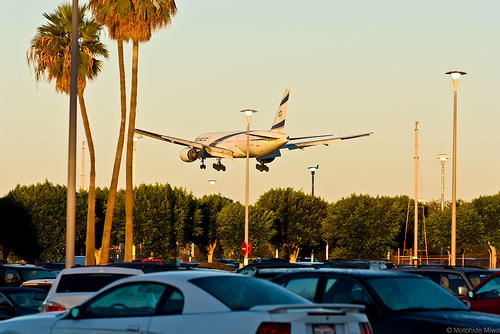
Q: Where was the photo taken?
A: It was taken at the parking lot.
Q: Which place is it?
A: It is a parking lot.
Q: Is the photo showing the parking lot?
A: Yes, it is showing the parking lot.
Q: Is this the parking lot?
A: Yes, it is the parking lot.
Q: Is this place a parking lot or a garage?
A: It is a parking lot.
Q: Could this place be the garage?
A: No, it is the parking lot.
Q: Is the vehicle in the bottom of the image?
A: Yes, the vehicle is in the bottom of the image.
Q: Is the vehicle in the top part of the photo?
A: No, the vehicle is in the bottom of the image.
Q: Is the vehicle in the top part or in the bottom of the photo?
A: The vehicle is in the bottom of the image.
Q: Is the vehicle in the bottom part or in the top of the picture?
A: The vehicle is in the bottom of the image.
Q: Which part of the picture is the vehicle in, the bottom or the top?
A: The vehicle is in the bottom of the image.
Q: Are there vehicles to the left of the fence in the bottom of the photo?
A: Yes, there is a vehicle to the left of the fence.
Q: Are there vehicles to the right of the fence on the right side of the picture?
A: No, the vehicle is to the left of the fence.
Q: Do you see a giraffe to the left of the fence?
A: No, there is a vehicle to the left of the fence.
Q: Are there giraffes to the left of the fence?
A: No, there is a vehicle to the left of the fence.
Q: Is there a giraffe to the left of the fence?
A: No, there is a vehicle to the left of the fence.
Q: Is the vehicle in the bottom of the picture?
A: Yes, the vehicle is in the bottom of the image.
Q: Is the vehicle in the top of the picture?
A: No, the vehicle is in the bottom of the image.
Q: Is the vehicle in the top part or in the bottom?
A: The vehicle is in the bottom of the image.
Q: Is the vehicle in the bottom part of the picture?
A: Yes, the vehicle is in the bottom of the image.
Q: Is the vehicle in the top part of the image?
A: No, the vehicle is in the bottom of the image.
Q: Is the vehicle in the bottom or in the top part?
A: The vehicle is in the bottom of the image.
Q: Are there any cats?
A: No, there are no cats.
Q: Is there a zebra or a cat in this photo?
A: No, there are no cats or zebras.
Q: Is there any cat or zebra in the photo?
A: No, there are no cats or zebras.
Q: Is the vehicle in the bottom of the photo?
A: Yes, the vehicle is in the bottom of the image.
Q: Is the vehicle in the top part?
A: No, the vehicle is in the bottom of the image.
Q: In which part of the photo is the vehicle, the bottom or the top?
A: The vehicle is in the bottom of the image.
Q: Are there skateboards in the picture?
A: No, there are no skateboards.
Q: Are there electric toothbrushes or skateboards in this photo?
A: No, there are no skateboards or electric toothbrushes.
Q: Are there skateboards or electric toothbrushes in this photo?
A: No, there are no skateboards or electric toothbrushes.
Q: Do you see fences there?
A: Yes, there is a fence.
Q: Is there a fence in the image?
A: Yes, there is a fence.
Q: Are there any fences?
A: Yes, there is a fence.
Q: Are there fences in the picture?
A: Yes, there is a fence.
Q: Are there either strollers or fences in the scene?
A: Yes, there is a fence.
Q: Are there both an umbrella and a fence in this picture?
A: No, there is a fence but no umbrellas.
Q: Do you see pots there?
A: No, there are no pots.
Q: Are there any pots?
A: No, there are no pots.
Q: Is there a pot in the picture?
A: No, there are no pots.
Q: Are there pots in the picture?
A: No, there are no pots.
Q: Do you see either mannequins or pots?
A: No, there are no pots or mannequins.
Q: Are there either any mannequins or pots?
A: No, there are no pots or mannequins.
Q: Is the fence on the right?
A: Yes, the fence is on the right of the image.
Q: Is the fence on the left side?
A: No, the fence is on the right of the image.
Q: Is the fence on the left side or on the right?
A: The fence is on the right of the image.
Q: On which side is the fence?
A: The fence is on the right of the image.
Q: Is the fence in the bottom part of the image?
A: Yes, the fence is in the bottom of the image.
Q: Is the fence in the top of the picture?
A: No, the fence is in the bottom of the image.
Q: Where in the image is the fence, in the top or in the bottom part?
A: The fence is in the bottom of the image.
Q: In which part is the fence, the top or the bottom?
A: The fence is in the bottom of the image.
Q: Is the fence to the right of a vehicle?
A: Yes, the fence is to the right of a vehicle.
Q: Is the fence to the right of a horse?
A: No, the fence is to the right of a vehicle.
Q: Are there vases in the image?
A: No, there are no vases.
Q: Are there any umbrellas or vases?
A: No, there are no vases or umbrellas.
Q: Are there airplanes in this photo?
A: Yes, there is an airplane.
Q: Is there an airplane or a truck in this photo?
A: Yes, there is an airplane.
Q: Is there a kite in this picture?
A: No, there are no kites.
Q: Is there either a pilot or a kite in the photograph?
A: No, there are no kites or pilots.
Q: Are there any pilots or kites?
A: No, there are no kites or pilots.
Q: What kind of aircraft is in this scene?
A: The aircraft is an airplane.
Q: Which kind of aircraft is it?
A: The aircraft is an airplane.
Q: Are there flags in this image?
A: No, there are no flags.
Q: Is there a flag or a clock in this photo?
A: No, there are no flags or clocks.